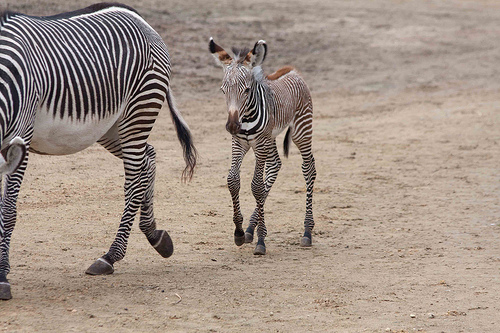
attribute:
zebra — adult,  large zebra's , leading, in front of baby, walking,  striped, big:
[3, 3, 197, 303]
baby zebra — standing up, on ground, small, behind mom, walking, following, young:
[207, 33, 320, 257]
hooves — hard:
[2, 230, 180, 303]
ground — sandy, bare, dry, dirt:
[2, 2, 497, 329]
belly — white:
[29, 107, 129, 157]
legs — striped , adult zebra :
[1, 134, 165, 282]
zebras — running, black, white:
[0, 2, 336, 312]